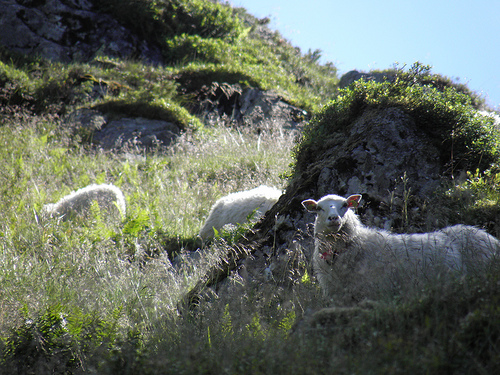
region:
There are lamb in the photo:
[44, 63, 496, 315]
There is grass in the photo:
[22, 59, 437, 373]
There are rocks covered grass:
[239, 71, 496, 300]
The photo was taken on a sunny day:
[48, 19, 453, 371]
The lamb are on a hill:
[39, 43, 466, 365]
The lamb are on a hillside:
[48, 15, 425, 345]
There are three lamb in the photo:
[21, 63, 463, 344]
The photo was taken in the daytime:
[28, 16, 491, 338]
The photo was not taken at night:
[31, 8, 496, 354]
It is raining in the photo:
[45, 14, 455, 371]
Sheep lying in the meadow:
[290, 179, 495, 344]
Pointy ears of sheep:
[294, 187, 375, 214]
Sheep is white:
[276, 174, 497, 332]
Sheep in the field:
[187, 170, 285, 257]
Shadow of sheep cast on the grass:
[157, 216, 196, 266]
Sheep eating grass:
[183, 179, 287, 259]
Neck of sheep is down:
[189, 209, 221, 257]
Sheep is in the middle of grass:
[27, 176, 132, 236]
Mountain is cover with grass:
[0, 1, 307, 116]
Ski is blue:
[296, 6, 499, 70]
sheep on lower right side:
[298, 191, 498, 316]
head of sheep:
[300, 191, 363, 229]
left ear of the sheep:
[346, 191, 359, 207]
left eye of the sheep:
[341, 200, 348, 210]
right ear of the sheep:
[301, 198, 316, 209]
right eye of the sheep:
[316, 206, 324, 213]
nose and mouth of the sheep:
[321, 213, 341, 230]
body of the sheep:
[370, 233, 473, 298]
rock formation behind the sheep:
[208, 81, 489, 311]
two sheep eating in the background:
[38, 178, 280, 246]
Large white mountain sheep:
[298, 182, 498, 344]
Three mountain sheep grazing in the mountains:
[37, 175, 499, 355]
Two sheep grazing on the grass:
[25, 140, 290, 268]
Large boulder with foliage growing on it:
[263, 66, 498, 263]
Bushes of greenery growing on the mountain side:
[3, 242, 214, 373]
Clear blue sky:
[305, 7, 497, 60]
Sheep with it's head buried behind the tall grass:
[185, 177, 285, 257]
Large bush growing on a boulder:
[140, 0, 258, 70]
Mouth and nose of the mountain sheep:
[322, 207, 345, 236]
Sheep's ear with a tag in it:
[343, 187, 366, 212]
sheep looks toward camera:
[236, 145, 397, 270]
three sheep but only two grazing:
[22, 138, 450, 285]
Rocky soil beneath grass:
[330, 72, 497, 199]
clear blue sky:
[265, 4, 495, 69]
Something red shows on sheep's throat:
[307, 226, 357, 281]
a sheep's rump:
[65, 168, 141, 235]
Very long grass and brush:
[10, 239, 172, 369]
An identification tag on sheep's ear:
[324, 176, 369, 225]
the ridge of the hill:
[223, 0, 340, 95]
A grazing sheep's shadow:
[138, 195, 227, 270]